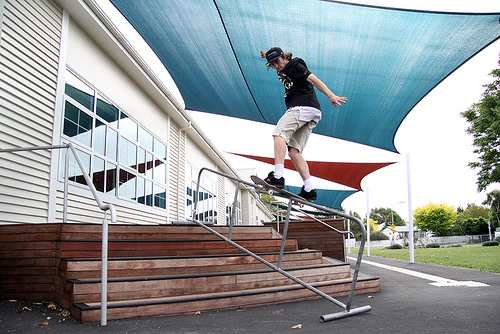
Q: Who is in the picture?
A: A skateboarder.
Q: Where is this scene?
A: Outside of a building.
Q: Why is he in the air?
A: He's doing a trick.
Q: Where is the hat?
A: On the man's head.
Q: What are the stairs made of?
A: Brick.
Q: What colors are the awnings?
A: Blue and red.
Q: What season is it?
A: Summer.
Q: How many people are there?
A: One.